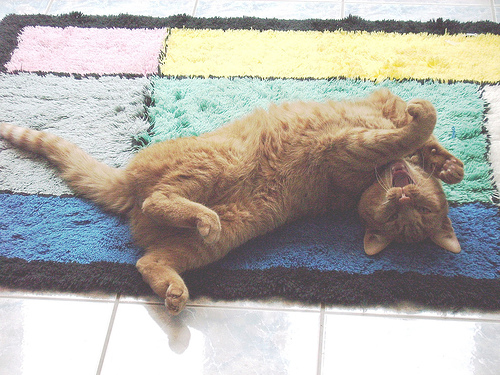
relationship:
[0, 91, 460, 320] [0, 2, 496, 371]
cat on floor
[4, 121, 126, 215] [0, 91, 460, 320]
tail of cat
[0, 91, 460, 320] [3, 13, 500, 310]
cat on rug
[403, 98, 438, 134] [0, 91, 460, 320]
paw of cat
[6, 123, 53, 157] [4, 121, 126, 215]
stripes on tail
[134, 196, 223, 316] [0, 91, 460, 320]
back paws of cat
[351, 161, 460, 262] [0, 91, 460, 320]
head of cat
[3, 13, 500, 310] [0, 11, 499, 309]
rug has trim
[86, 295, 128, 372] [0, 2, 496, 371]
line on floor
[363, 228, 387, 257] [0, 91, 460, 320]
ear of cat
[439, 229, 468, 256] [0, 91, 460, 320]
ear of cat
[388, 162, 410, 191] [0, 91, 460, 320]
mouth of cat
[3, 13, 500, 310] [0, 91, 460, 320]
rug under cat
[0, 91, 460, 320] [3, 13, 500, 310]
cat laying on rug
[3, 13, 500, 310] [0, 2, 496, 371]
rug on floor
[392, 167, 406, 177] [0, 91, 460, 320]
teeth on cat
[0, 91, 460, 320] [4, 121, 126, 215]
cat has a tail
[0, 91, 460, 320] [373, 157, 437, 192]
cat has whiskers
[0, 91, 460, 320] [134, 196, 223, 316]
cat has back paws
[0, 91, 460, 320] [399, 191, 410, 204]
cat has a nose